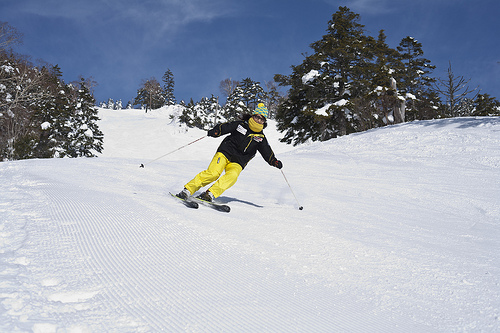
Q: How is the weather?
A: It is sunny.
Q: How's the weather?
A: It is sunny.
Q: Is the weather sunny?
A: Yes, it is sunny.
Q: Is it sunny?
A: Yes, it is sunny.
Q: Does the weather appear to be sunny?
A: Yes, it is sunny.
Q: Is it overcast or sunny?
A: It is sunny.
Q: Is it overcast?
A: No, it is sunny.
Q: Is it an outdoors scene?
A: Yes, it is outdoors.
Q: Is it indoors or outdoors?
A: It is outdoors.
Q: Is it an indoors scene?
A: No, it is outdoors.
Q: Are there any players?
A: No, there are no players.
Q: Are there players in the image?
A: No, there are no players.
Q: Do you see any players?
A: No, there are no players.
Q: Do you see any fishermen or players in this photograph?
A: No, there are no players or fishermen.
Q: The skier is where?
A: The skier is in the snow.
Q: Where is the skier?
A: The skier is in the snow.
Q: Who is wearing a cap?
A: The skier is wearing a cap.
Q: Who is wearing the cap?
A: The skier is wearing a cap.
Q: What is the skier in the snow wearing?
A: The skier is wearing a cap.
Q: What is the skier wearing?
A: The skier is wearing a cap.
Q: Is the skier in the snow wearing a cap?
A: Yes, the skier is wearing a cap.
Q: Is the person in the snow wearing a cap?
A: Yes, the skier is wearing a cap.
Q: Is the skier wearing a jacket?
A: No, the skier is wearing a cap.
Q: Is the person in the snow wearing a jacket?
A: No, the skier is wearing a cap.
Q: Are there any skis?
A: Yes, there are skis.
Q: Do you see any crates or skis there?
A: Yes, there are skis.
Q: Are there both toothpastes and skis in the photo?
A: No, there are skis but no toothpastes.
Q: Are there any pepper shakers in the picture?
A: No, there are no pepper shakers.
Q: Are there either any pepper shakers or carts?
A: No, there are no pepper shakers or carts.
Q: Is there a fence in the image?
A: No, there are no fences.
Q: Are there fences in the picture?
A: No, there are no fences.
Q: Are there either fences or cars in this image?
A: No, there are no fences or cars.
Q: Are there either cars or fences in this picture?
A: No, there are no fences or cars.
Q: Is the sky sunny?
A: Yes, the sky is sunny.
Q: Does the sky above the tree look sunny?
A: Yes, the sky is sunny.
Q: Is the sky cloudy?
A: No, the sky is sunny.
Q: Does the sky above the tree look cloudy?
A: No, the sky is sunny.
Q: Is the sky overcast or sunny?
A: The sky is sunny.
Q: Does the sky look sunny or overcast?
A: The sky is sunny.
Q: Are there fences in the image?
A: No, there are no fences.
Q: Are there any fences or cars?
A: No, there are no fences or cars.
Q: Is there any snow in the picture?
A: Yes, there is snow.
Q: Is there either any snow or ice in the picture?
A: Yes, there is snow.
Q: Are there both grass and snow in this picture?
A: No, there is snow but no grass.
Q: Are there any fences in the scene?
A: No, there are no fences.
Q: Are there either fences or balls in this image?
A: No, there are no fences or balls.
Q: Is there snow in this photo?
A: Yes, there is snow.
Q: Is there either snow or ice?
A: Yes, there is snow.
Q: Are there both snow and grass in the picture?
A: No, there is snow but no grass.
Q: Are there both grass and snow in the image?
A: No, there is snow but no grass.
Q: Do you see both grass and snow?
A: No, there is snow but no grass.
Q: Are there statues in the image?
A: No, there are no statues.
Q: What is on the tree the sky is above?
A: The snow is on the tree.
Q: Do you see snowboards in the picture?
A: No, there are no snowboards.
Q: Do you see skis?
A: Yes, there are skis.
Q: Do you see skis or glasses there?
A: Yes, there are skis.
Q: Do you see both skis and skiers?
A: Yes, there are both skis and a skier.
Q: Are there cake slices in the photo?
A: No, there are no cake slices.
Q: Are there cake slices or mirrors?
A: No, there are no cake slices or mirrors.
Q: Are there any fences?
A: No, there are no fences.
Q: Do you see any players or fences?
A: No, there are no fences or players.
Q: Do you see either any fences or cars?
A: No, there are no fences or cars.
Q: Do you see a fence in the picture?
A: No, there are no fences.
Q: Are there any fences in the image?
A: No, there are no fences.